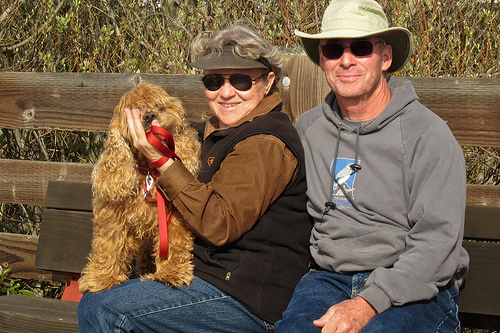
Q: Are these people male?
A: No, they are both male and female.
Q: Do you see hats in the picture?
A: Yes, there is a hat.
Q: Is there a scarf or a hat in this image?
A: Yes, there is a hat.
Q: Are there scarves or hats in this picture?
A: Yes, there is a hat.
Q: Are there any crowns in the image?
A: No, there are no crowns.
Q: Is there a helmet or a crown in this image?
A: No, there are no crowns or helmets.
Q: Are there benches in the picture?
A: Yes, there is a bench.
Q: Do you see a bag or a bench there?
A: Yes, there is a bench.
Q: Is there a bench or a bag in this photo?
A: Yes, there is a bench.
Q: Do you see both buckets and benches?
A: No, there is a bench but no buckets.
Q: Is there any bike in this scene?
A: No, there are no bikes.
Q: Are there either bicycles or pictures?
A: No, there are no bicycles or pictures.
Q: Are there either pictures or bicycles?
A: No, there are no bicycles or pictures.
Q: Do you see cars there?
A: No, there are no cars.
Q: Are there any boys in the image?
A: No, there are no boys.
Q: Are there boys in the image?
A: No, there are no boys.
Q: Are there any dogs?
A: Yes, there is a dog.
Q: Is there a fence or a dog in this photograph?
A: Yes, there is a dog.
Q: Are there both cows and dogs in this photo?
A: No, there is a dog but no cows.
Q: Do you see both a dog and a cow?
A: No, there is a dog but no cows.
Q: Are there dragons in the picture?
A: No, there are no dragons.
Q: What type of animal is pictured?
A: The animal is a dog.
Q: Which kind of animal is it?
A: The animal is a dog.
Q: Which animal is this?
A: This is a dog.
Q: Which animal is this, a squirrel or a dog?
A: This is a dog.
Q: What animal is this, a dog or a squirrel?
A: This is a dog.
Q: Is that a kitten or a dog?
A: That is a dog.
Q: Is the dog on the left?
A: Yes, the dog is on the left of the image.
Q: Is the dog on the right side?
A: No, the dog is on the left of the image.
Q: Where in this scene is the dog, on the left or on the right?
A: The dog is on the left of the image.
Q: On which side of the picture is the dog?
A: The dog is on the left of the image.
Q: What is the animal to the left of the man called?
A: The animal is a dog.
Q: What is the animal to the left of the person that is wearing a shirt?
A: The animal is a dog.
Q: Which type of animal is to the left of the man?
A: The animal is a dog.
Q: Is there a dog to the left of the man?
A: Yes, there is a dog to the left of the man.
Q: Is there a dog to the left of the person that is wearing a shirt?
A: Yes, there is a dog to the left of the man.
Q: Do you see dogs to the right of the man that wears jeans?
A: No, the dog is to the left of the man.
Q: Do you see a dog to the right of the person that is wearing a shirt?
A: No, the dog is to the left of the man.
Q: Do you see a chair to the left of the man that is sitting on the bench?
A: No, there is a dog to the left of the man.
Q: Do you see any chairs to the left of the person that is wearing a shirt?
A: No, there is a dog to the left of the man.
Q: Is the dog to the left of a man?
A: Yes, the dog is to the left of a man.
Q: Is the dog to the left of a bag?
A: No, the dog is to the left of a man.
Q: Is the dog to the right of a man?
A: No, the dog is to the left of a man.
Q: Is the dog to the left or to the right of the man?
A: The dog is to the left of the man.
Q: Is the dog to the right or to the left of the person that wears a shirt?
A: The dog is to the left of the man.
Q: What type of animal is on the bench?
A: The animal is a dog.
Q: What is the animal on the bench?
A: The animal is a dog.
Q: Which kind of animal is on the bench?
A: The animal is a dog.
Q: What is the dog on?
A: The dog is on the bench.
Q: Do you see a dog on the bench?
A: Yes, there is a dog on the bench.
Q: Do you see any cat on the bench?
A: No, there is a dog on the bench.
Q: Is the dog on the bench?
A: Yes, the dog is on the bench.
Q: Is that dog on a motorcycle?
A: No, the dog is on the bench.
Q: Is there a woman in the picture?
A: Yes, there is a woman.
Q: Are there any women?
A: Yes, there is a woman.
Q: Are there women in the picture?
A: Yes, there is a woman.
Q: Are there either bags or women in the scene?
A: Yes, there is a woman.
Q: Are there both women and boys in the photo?
A: No, there is a woman but no boys.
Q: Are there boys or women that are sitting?
A: Yes, the woman is sitting.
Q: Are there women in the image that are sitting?
A: Yes, there is a woman that is sitting.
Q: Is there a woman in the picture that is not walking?
A: Yes, there is a woman that is sitting.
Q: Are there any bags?
A: No, there are no bags.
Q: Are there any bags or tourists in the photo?
A: No, there are no bags or tourists.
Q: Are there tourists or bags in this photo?
A: No, there are no bags or tourists.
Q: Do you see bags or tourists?
A: No, there are no bags or tourists.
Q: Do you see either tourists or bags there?
A: No, there are no bags or tourists.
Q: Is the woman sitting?
A: Yes, the woman is sitting.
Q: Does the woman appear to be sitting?
A: Yes, the woman is sitting.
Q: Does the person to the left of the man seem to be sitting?
A: Yes, the woman is sitting.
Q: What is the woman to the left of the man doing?
A: The woman is sitting.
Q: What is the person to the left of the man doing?
A: The woman is sitting.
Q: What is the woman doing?
A: The woman is sitting.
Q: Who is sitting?
A: The woman is sitting.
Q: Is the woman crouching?
A: No, the woman is sitting.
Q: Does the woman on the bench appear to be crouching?
A: No, the woman is sitting.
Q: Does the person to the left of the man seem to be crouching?
A: No, the woman is sitting.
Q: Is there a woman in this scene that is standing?
A: No, there is a woman but she is sitting.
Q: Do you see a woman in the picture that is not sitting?
A: No, there is a woman but she is sitting.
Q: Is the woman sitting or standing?
A: The woman is sitting.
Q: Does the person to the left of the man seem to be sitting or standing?
A: The woman is sitting.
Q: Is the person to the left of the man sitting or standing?
A: The woman is sitting.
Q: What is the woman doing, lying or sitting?
A: The woman is sitting.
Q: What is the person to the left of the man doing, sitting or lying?
A: The woman is sitting.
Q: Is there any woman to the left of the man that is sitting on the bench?
A: Yes, there is a woman to the left of the man.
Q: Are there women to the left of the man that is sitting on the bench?
A: Yes, there is a woman to the left of the man.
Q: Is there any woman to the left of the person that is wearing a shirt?
A: Yes, there is a woman to the left of the man.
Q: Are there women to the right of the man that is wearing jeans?
A: No, the woman is to the left of the man.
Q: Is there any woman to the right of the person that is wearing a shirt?
A: No, the woman is to the left of the man.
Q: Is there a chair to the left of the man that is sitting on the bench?
A: No, there is a woman to the left of the man.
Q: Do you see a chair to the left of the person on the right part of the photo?
A: No, there is a woman to the left of the man.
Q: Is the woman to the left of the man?
A: Yes, the woman is to the left of the man.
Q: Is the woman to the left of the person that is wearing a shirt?
A: Yes, the woman is to the left of the man.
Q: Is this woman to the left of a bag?
A: No, the woman is to the left of the man.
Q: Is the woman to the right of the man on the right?
A: No, the woman is to the left of the man.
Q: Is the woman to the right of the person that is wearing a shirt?
A: No, the woman is to the left of the man.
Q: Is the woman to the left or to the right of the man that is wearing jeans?
A: The woman is to the left of the man.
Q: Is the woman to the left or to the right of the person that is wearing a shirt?
A: The woman is to the left of the man.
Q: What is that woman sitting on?
A: The woman is sitting on the bench.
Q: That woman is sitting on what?
A: The woman is sitting on the bench.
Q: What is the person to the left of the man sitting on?
A: The woman is sitting on the bench.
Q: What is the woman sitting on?
A: The woman is sitting on the bench.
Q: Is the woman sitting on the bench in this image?
A: Yes, the woman is sitting on the bench.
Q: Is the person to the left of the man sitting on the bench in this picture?
A: Yes, the woman is sitting on the bench.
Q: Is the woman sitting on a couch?
A: No, the woman is sitting on the bench.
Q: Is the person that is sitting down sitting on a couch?
A: No, the woman is sitting on the bench.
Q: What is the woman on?
A: The woman is on the bench.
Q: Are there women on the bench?
A: Yes, there is a woman on the bench.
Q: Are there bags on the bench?
A: No, there is a woman on the bench.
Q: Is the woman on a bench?
A: Yes, the woman is on a bench.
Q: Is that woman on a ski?
A: No, the woman is on a bench.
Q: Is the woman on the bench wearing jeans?
A: Yes, the woman is wearing jeans.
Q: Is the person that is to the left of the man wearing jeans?
A: Yes, the woman is wearing jeans.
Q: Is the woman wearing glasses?
A: No, the woman is wearing jeans.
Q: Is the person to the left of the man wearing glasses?
A: No, the woman is wearing jeans.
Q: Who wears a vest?
A: The woman wears a vest.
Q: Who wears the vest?
A: The woman wears a vest.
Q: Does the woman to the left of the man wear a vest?
A: Yes, the woman wears a vest.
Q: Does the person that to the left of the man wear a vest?
A: Yes, the woman wears a vest.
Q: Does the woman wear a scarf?
A: No, the woman wears a vest.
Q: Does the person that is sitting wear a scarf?
A: No, the woman wears a vest.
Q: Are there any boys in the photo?
A: No, there are no boys.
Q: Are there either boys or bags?
A: No, there are no boys or bags.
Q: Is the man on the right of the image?
A: Yes, the man is on the right of the image.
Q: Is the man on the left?
A: No, the man is on the right of the image.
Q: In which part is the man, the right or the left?
A: The man is on the right of the image.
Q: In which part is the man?
A: The man is on the right of the image.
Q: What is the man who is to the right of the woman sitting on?
A: The man is sitting on the bench.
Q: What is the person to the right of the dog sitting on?
A: The man is sitting on the bench.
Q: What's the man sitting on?
A: The man is sitting on the bench.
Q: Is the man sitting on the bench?
A: Yes, the man is sitting on the bench.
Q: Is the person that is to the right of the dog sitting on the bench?
A: Yes, the man is sitting on the bench.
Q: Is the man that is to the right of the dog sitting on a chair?
A: No, the man is sitting on the bench.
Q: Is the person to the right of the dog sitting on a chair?
A: No, the man is sitting on the bench.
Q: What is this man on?
A: The man is on the bench.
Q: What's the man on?
A: The man is on the bench.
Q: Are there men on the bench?
A: Yes, there is a man on the bench.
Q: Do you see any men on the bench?
A: Yes, there is a man on the bench.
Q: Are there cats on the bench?
A: No, there is a man on the bench.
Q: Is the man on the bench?
A: Yes, the man is on the bench.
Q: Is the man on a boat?
A: No, the man is on the bench.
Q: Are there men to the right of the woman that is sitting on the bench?
A: Yes, there is a man to the right of the woman.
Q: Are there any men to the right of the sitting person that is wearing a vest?
A: Yes, there is a man to the right of the woman.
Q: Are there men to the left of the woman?
A: No, the man is to the right of the woman.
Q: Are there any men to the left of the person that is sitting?
A: No, the man is to the right of the woman.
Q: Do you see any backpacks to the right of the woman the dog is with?
A: No, there is a man to the right of the woman.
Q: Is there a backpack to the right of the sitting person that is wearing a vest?
A: No, there is a man to the right of the woman.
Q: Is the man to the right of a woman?
A: Yes, the man is to the right of a woman.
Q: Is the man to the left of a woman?
A: No, the man is to the right of a woman.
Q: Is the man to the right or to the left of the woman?
A: The man is to the right of the woman.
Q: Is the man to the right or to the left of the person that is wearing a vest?
A: The man is to the right of the woman.